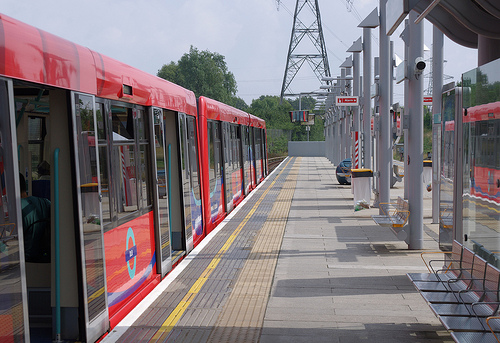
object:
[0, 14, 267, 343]
train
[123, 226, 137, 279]
graphic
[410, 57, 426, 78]
camera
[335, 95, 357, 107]
sign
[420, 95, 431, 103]
sign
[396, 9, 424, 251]
metal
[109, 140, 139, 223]
window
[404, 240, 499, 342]
bench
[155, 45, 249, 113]
tree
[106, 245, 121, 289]
red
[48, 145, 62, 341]
pole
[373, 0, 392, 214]
pole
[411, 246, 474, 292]
seat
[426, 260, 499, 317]
seat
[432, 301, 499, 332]
seat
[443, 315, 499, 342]
seat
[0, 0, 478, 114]
sky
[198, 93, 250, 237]
train cars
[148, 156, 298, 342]
line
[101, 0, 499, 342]
platform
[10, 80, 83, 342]
door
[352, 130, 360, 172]
traffic pole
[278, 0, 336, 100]
tower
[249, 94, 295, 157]
trees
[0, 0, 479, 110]
clouds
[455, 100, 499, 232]
reflection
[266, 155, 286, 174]
track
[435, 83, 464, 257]
display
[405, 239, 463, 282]
seat